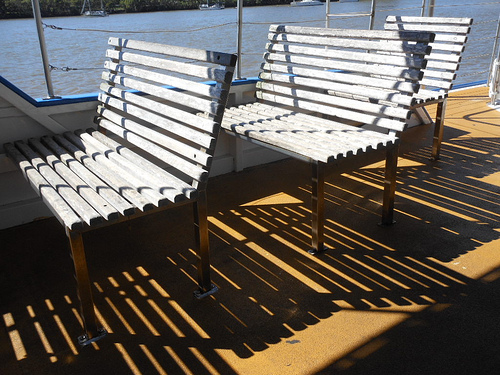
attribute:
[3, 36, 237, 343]
bench — wooden, weather worn, gray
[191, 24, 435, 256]
bench — wooden, weather worn, gray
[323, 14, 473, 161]
bench — wooden, weather worn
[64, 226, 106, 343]
leg — metal, dark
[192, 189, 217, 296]
leg — metal, dark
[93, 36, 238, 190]
bench back — white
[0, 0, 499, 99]
body of water — large, partially in view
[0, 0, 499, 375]
boat — medium sized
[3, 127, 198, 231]
seat — white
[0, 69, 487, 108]
edge — blue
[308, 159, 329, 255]
leg — metal, dark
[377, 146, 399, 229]
leg — metal, dark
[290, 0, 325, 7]
boat — white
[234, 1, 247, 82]
pole — metal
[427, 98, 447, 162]
leg — metal, dark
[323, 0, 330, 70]
pole — metal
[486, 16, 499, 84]
pole — metal